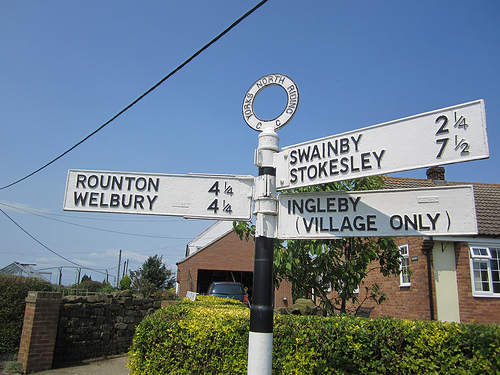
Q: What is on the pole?
A: Street signs.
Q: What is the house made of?
A: Bricks.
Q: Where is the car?
A: In garage.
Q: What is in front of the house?
A: Bushes.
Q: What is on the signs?
A: Street directions.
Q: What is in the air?
A: Wire.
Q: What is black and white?
A: The sign.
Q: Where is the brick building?
A: Behind the signs.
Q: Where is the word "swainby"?
A: On the sign.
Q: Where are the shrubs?
A: Behind the sign.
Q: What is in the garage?
A: A car.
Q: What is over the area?
A: Power line.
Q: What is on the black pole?
A: Three signs.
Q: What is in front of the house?
A: Sign.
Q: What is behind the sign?
A: House.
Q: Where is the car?
A: In garage.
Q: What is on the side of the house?
A: Fence.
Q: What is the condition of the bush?
A: Trimmed.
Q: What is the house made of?
A: Brick.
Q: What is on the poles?
A: Street signs.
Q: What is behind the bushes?
A: A house.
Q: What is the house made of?
A: Bricks.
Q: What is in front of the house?
A: Bushes.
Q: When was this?
A: Daytime.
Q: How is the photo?
A: Clear.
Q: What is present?
A: A post.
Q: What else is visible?
A: A house.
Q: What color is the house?
A: Brown.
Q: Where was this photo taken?
A: At a street intersection.